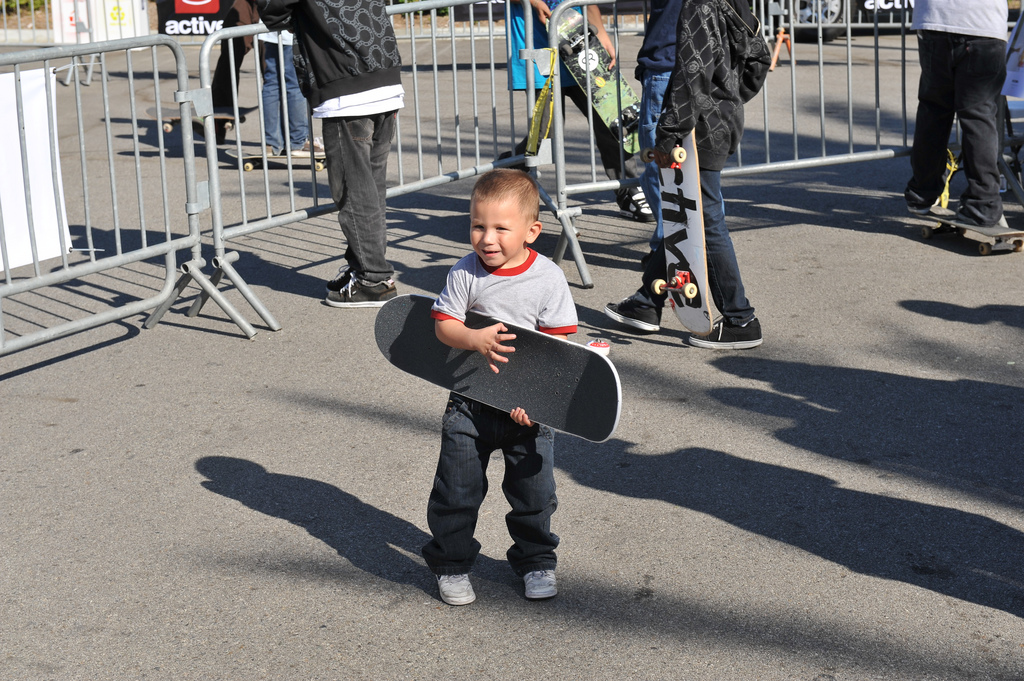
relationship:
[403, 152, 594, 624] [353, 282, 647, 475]
boy holding board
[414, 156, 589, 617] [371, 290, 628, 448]
boy holding board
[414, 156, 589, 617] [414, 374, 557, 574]
boy wearing jeans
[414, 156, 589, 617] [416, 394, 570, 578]
boy wearing pants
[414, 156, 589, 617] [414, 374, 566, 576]
boy wearing jeans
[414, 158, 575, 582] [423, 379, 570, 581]
boy wearing jeans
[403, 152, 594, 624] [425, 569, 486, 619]
boy wearing shoe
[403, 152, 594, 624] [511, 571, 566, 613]
boy wearing shoe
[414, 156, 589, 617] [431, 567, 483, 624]
boy wearing shoe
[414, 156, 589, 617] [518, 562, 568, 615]
boy wearing shoe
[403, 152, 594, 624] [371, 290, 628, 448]
boy holding board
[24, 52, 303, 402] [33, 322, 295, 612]
fences on street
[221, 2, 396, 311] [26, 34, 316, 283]
man on fence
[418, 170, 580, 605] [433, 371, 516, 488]
boy with shorts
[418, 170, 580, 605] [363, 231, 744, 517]
boy holding skateboard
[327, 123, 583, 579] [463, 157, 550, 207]
boy with hair